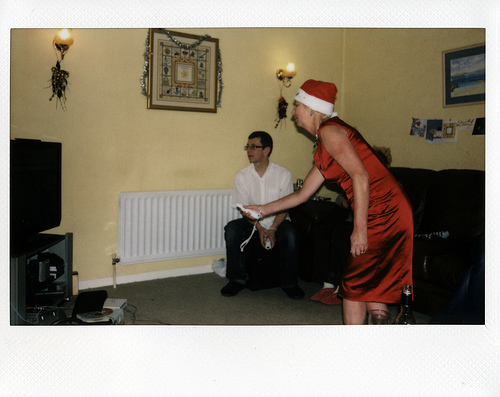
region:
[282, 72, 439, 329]
Woman wearing a red shirt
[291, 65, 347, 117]
Hat on woman's head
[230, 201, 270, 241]
Remote in woman's hand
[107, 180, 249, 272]
Radiator against the wall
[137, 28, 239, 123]
Picture on the wall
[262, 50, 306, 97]
Lamp on the wall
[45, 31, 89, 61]
Lamp on the wall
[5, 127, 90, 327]
Flat screen tv on stand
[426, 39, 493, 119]
Picture on the wall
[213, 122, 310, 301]
Man sitting on couch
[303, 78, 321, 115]
This woman is wearing a Santa hat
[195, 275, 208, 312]
There is light grey carpeting here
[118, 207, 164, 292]
There is a white vent here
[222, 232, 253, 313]
This man is wearing a pair of jeans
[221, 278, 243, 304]
This man is wearing a pair of shoes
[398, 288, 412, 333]
There is a bottle in the background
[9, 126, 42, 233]
There is a television that is here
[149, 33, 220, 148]
There is a photo here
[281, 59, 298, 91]
There is a lamp on the wall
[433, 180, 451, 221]
There is a leather sofa here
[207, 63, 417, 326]
A woman wearing a santa hat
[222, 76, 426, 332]
A woman playing the wii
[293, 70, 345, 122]
A red and white santa hat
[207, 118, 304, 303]
A man sitting down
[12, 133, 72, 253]
A black television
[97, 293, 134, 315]
A white wii console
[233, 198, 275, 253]
White wii controllers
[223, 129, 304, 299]
A man wearing glasses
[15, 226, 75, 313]
A grey entertainment stand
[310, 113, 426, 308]
A red dress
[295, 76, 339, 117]
Christmas hat on a head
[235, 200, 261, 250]
A video game controller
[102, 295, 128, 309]
Video game console on the floor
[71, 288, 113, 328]
A case of discs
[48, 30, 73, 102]
A light on a light holder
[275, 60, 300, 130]
A light inside of a container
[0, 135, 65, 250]
A TV on a stand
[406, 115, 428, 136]
A small quilt on a string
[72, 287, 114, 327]
CD's in a case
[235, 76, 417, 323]
woman plays the Nintendo Wii game system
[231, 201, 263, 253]
Game controller is held by woman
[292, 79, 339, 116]
Santa Claus hat is worn by woman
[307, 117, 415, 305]
dress is worn by woman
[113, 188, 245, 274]
radiator is attached to the wall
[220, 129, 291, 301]
man wears glasses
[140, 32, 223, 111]
picture frame hangs on wall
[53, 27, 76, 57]
light is turned on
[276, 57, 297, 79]
light is turned on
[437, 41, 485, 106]
picture hangs on wall